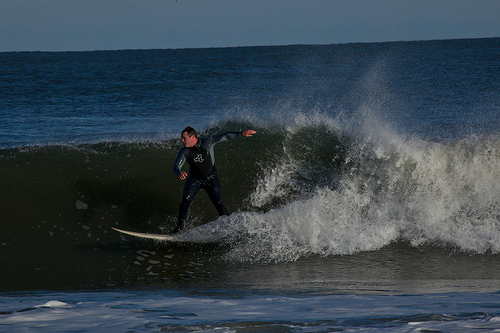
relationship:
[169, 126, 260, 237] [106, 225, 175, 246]
man riding surfboard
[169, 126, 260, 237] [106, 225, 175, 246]
man on top of surfboard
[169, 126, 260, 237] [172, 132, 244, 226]
man wearing wet suit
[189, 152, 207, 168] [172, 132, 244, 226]
logo on front of wet suit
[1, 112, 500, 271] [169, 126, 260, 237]
wave propelling man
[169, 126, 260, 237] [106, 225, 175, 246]
man standing on surfboard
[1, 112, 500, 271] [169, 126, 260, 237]
wave splashing man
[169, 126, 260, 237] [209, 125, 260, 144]
man has left arm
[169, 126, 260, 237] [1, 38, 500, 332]
man surfing in water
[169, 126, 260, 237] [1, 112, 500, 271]
man on top of wave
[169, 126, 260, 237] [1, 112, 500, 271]
man riding wave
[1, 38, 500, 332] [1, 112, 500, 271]
water has wave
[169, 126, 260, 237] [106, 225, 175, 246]
man surfing on surfboard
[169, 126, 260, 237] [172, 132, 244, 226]
man inside of wet suit